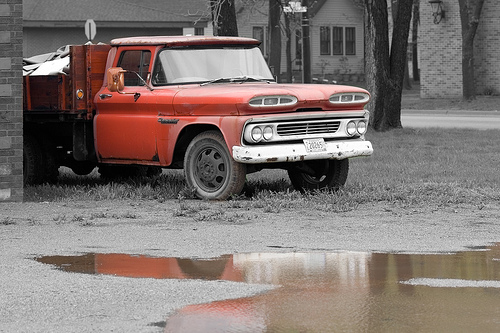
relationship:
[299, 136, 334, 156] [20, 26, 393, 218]
license plate on truck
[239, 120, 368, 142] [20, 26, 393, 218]
headlights on truck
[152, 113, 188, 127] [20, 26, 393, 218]
logo on truck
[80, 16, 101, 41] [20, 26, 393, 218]
street sign behind truck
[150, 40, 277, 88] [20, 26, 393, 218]
windshield on truck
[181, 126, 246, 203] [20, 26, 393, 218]
front tire on truck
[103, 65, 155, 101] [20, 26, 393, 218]
mirror on truck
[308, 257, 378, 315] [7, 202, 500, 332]
water on ground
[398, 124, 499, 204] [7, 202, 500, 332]
grass on ground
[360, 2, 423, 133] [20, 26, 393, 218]
tree near truck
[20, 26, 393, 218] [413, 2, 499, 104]
truck next to building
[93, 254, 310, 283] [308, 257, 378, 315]
truck reflection in water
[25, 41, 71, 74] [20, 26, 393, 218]
cargo on truck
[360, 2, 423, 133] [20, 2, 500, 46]
tree in background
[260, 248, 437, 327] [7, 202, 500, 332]
puddle on road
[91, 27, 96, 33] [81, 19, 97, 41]
back of a street sign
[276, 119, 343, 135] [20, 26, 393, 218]
grill on truck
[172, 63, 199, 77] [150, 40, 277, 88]
light on windshield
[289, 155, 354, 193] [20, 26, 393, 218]
wheel of a truck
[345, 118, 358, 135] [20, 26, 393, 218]
light of a truck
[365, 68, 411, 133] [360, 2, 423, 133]
stem of a tree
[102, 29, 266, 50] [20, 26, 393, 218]
bonnet of a truck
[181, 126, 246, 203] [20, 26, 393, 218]
tire of a truck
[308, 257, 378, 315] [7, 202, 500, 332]
water of ground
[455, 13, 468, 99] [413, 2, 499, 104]
edge of a building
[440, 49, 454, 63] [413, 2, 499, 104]
part of a building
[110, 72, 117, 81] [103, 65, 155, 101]
part of a mirror